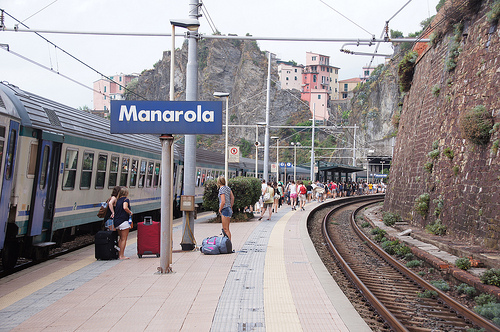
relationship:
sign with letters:
[107, 99, 224, 135] [118, 103, 215, 126]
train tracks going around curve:
[313, 178, 498, 330] [320, 147, 498, 288]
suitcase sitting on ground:
[135, 216, 162, 259] [11, 205, 497, 328]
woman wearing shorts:
[209, 169, 244, 254] [212, 205, 236, 219]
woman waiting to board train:
[209, 169, 244, 254] [0, 74, 268, 256]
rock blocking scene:
[90, 10, 323, 162] [0, 3, 499, 331]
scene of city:
[0, 3, 499, 331] [91, 34, 384, 147]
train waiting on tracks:
[2, 79, 289, 260] [0, 240, 78, 278]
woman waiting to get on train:
[118, 188, 131, 256] [0, 73, 243, 273]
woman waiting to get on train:
[100, 185, 120, 258] [0, 73, 243, 273]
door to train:
[34, 136, 60, 240] [0, 75, 210, 254]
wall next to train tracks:
[385, 15, 498, 255] [313, 197, 498, 331]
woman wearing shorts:
[214, 175, 234, 254] [217, 206, 233, 220]